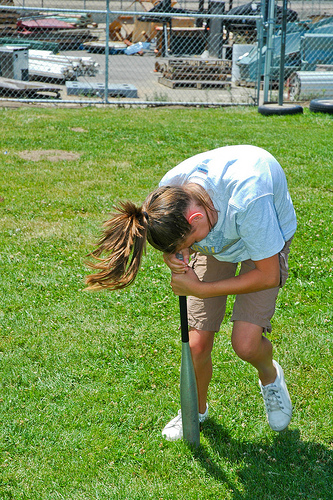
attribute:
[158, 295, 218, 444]
baseball bat — silver, black, metal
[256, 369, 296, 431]
shoe — white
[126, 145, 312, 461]
woman — bent over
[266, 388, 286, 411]
shoestring — white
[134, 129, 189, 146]
grass — green, here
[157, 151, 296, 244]
shirt — gray, white, short sleeved, light, designed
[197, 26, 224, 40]
fence — chain link, silver, distant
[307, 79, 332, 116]
tire — black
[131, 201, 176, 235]
rubber band — black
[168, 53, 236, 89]
pallets — stacked, wooden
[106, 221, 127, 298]
ponytail — hanging to side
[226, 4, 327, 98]
trash — piled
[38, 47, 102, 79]
metal — stacked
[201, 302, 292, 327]
brown shorts — khakis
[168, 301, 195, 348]
handle — black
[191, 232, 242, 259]
design — yellow, gray